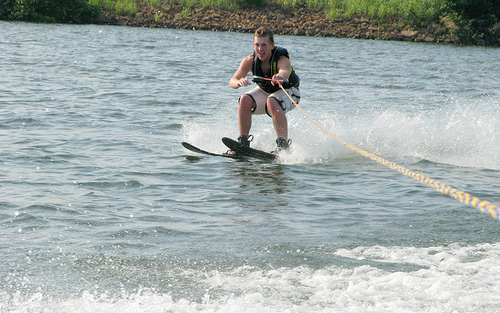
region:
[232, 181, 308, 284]
The water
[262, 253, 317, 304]
The water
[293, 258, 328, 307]
The water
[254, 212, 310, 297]
The water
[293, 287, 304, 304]
The water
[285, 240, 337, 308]
The water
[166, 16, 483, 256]
man on water skis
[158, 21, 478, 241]
man water skiing with tow rope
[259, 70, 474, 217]
tow rope for water skier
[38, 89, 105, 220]
ripples and waves on the water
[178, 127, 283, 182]
pair of water skis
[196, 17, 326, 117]
man in a life jacket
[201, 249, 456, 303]
foamy wake of the boat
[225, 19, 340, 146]
man in white swim trunks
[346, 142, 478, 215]
yellow and blue rope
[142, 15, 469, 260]
man enjoying his water skiing adventure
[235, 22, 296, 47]
Man has brown hair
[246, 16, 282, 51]
Man's hair is curly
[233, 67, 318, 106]
Man holding ski rope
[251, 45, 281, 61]
Man has white teeth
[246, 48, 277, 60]
Man's teeth are straight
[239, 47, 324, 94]
Man wearing life vest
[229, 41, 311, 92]
Man's life vest is black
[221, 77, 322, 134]
Man wearing white shorts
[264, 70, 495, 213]
Tow rope is pulling skier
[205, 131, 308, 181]
Man's ski is black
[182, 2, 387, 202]
a man waterskiing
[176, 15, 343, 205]
a man skiing on water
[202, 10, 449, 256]
a man holding onto rope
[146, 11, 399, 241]
a man on the water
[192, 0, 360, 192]
a man wearing shorts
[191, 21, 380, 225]
a man wearing life jacket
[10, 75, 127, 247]
a body of water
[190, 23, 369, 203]
a person on the water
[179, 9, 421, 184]
a man bent down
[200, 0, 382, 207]
a man skiing outside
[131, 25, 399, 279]
a man is kneeboarding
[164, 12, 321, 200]
a man is kneeboarding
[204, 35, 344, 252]
a man is kneeboarding